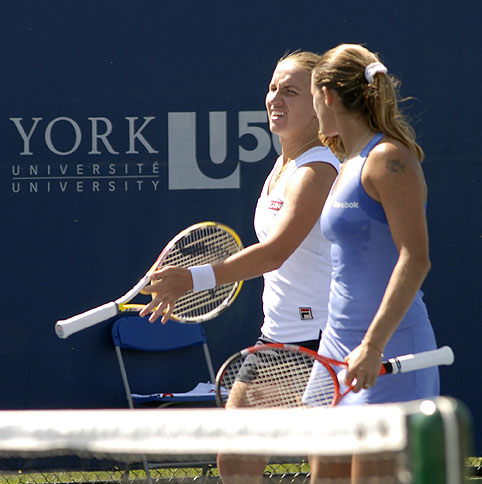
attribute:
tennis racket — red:
[221, 343, 365, 405]